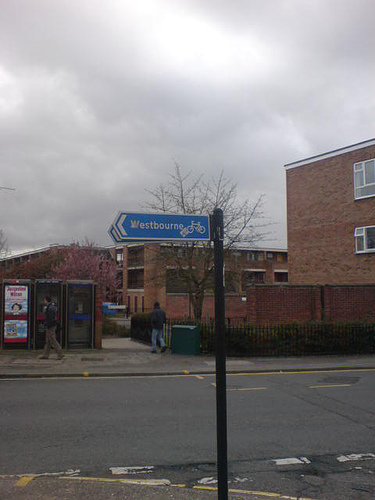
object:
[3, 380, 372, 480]
cows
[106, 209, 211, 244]
blue sign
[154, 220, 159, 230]
letter "b"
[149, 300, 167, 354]
guy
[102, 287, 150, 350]
entrance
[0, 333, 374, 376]
sidewalk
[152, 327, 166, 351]
jeans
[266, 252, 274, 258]
window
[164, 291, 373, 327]
red wall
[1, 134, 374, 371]
urban area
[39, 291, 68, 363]
guy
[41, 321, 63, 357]
pants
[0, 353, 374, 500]
street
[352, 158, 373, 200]
window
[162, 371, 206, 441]
side walk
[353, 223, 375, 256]
window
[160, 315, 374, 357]
fence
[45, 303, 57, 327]
pocket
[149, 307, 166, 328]
jacket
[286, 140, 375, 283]
building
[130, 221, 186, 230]
letter